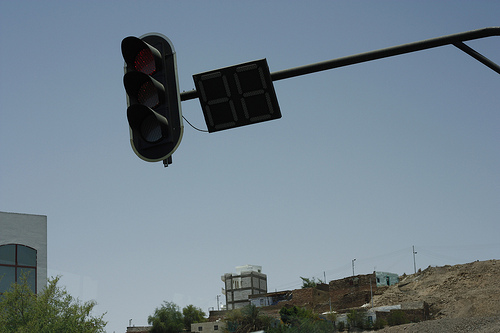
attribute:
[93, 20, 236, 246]
lights — row, three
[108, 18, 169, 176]
cones — black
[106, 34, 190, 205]
light — traffic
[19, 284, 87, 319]
tree — top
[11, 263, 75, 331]
leaves — green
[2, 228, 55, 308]
windows — small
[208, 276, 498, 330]
terrain — elevated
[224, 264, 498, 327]
terrain — elevated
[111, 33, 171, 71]
light — red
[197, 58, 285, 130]
sign — black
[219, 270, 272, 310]
building — white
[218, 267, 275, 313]
building — tall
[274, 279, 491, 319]
hill — dirt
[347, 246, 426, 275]
poles — electric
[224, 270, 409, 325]
hill — top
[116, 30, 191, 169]
light — black, street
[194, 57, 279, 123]
sign — metal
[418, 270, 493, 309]
dirt — exposed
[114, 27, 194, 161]
light — traffic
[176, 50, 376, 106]
pole — end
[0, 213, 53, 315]
building — white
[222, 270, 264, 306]
building — white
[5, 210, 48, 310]
building — white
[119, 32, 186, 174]
light — traffic, metal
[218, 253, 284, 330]
building — large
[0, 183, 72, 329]
bilding — large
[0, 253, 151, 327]
tree — green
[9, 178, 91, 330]
building — large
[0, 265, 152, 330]
tree — green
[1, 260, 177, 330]
tree — green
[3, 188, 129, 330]
building — large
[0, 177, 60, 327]
building — gray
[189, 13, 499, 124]
pole — black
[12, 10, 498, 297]
sky — clear, light blue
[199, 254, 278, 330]
biulding — black, white, small, distant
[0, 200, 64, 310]
biulding — gray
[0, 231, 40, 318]
window — brown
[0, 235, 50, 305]
window — brown, gray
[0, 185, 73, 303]
wall — gray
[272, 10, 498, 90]
pole — black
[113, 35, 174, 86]
light — red, off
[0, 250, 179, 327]
leaves — green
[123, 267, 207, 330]
branches — three, distant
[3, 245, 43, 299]
windows — tinted, glass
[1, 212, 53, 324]
building — white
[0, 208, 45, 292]
building — white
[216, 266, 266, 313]
building — square, tanned, black